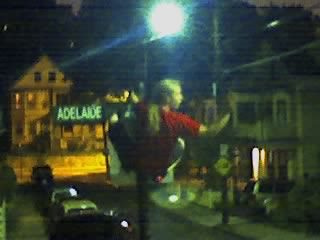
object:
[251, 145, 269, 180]
light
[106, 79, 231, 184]
man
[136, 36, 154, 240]
lamppost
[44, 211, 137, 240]
car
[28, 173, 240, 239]
street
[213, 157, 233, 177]
sign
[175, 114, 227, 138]
arm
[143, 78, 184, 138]
hair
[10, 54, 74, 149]
facade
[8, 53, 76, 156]
building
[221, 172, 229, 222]
signpost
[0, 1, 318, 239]
scene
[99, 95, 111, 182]
pole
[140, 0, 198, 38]
light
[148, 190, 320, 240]
sidewalk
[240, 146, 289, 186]
porch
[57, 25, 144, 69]
glare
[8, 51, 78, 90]
roof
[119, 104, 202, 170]
shirt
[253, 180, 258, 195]
glare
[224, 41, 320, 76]
line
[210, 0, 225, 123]
pole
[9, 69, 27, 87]
part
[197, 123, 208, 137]
part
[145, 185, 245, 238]
part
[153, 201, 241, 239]
edge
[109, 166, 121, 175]
part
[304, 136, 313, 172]
wall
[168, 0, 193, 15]
part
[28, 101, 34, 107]
part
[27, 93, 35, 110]
window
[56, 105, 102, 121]
letter